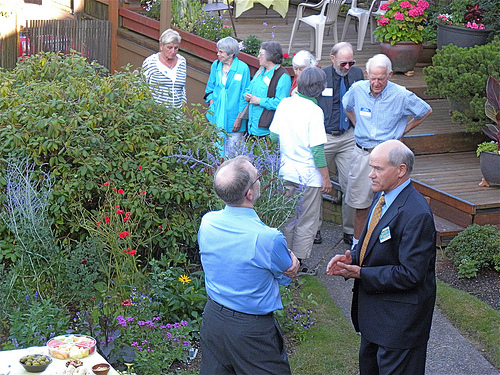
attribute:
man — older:
[337, 51, 432, 146]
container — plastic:
[45, 332, 97, 359]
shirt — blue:
[196, 203, 298, 314]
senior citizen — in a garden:
[142, 27, 194, 109]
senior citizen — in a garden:
[173, 147, 310, 373]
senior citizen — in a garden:
[264, 60, 334, 278]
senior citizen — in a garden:
[202, 33, 250, 135]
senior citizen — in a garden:
[243, 37, 290, 149]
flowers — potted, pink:
[378, 0, 430, 28]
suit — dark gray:
[304, 186, 478, 373]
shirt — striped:
[140, 55, 194, 108]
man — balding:
[305, 135, 460, 355]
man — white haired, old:
[337, 48, 435, 256]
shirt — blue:
[335, 75, 432, 158]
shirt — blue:
[195, 204, 286, 314]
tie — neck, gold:
[340, 201, 390, 287]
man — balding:
[185, 160, 305, 374]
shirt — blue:
[198, 203, 281, 307]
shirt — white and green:
[312, 145, 327, 173]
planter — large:
[373, 36, 423, 75]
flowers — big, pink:
[372, 0, 426, 42]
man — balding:
[357, 136, 427, 228]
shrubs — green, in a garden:
[2, 45, 312, 329]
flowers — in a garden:
[4, 149, 200, 364]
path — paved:
[429, 328, 484, 369]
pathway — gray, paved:
[306, 223, 496, 373]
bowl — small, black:
[18, 353, 55, 373]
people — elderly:
[200, 116, 445, 367]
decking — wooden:
[385, 144, 500, 253]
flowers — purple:
[102, 274, 219, 354]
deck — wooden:
[441, 173, 490, 218]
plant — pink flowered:
[375, 9, 425, 44]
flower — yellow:
[170, 262, 189, 286]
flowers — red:
[85, 168, 149, 280]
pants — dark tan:
[279, 176, 321, 260]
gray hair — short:
[158, 26, 184, 46]